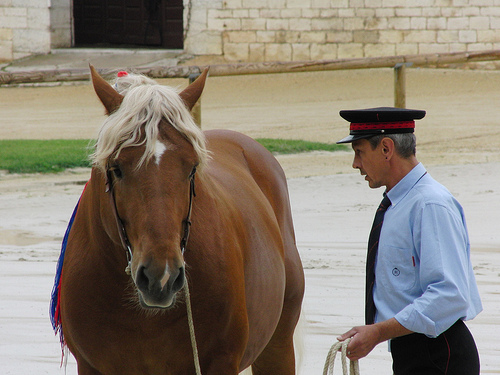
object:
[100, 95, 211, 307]
face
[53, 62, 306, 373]
horse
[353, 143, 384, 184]
face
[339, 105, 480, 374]
man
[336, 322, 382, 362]
hand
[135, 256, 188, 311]
nose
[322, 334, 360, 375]
rope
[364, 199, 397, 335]
tie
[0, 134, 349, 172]
grass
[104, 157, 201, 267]
bridle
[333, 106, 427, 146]
cap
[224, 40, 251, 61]
bricks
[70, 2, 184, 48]
doorway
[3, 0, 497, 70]
wall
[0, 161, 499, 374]
ground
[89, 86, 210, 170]
hair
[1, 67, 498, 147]
fence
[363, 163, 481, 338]
shirt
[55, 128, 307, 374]
body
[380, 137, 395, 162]
ear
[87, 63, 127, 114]
ear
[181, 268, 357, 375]
rope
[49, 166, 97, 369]
blanket